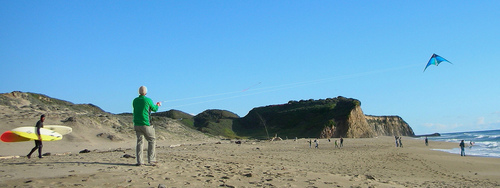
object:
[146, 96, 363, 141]
grass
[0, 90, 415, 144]
cliffs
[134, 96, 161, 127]
green shirt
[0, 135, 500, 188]
ground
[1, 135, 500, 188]
sand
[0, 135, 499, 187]
beach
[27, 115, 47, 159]
man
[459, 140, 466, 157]
man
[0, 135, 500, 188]
shore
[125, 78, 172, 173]
man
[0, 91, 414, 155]
hills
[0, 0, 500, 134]
sky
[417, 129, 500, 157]
waves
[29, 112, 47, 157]
surfer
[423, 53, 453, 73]
kite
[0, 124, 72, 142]
carrying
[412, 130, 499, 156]
water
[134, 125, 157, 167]
pants